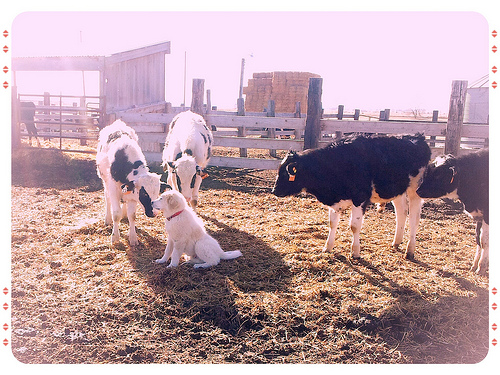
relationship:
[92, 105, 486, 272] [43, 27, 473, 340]
animals in photo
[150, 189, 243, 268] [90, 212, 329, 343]
animal on ground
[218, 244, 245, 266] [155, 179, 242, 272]
tail of dog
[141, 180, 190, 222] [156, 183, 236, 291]
head of dog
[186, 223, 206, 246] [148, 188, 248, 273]
fur of dog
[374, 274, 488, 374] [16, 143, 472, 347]
shadow on ground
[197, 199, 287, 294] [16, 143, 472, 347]
shadow on ground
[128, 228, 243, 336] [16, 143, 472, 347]
shadow on ground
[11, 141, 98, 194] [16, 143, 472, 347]
shadow on ground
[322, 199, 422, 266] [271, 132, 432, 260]
legs of animal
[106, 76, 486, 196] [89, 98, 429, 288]
fence behind animals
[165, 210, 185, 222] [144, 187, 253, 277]
collar ob dog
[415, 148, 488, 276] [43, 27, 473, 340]
animal entering photo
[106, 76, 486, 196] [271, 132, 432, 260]
fence keeping animal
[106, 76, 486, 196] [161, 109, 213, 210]
fence keeping animal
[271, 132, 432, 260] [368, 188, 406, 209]
animal with belly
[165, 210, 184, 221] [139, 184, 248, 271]
collar on dog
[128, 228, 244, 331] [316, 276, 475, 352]
shadow on dirt